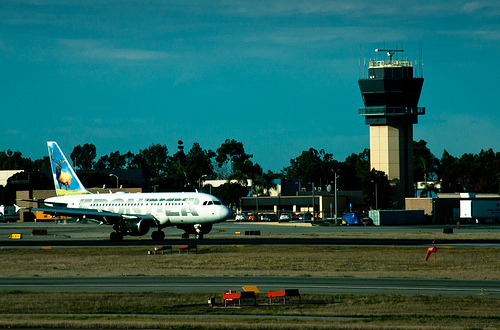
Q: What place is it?
A: It is an airport.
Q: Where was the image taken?
A: It was taken at the airport.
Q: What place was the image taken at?
A: It was taken at the airport.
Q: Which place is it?
A: It is an airport.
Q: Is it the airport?
A: Yes, it is the airport.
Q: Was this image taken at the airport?
A: Yes, it was taken in the airport.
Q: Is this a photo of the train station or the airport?
A: It is showing the airport.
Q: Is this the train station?
A: No, it is the airport.